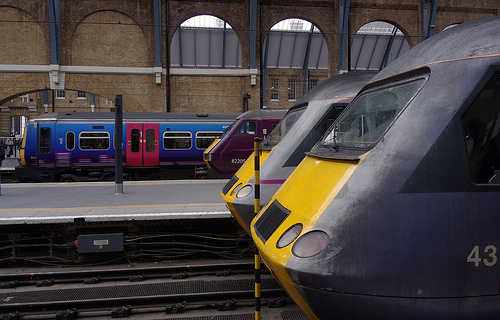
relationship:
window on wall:
[161, 11, 244, 70] [2, 0, 499, 115]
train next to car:
[201, 106, 298, 174] [14, 115, 238, 179]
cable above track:
[5, 230, 262, 256] [1, 257, 278, 311]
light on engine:
[289, 227, 331, 259] [248, 19, 498, 319]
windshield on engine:
[320, 75, 427, 146] [248, 19, 498, 319]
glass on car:
[162, 130, 192, 151] [14, 115, 238, 179]